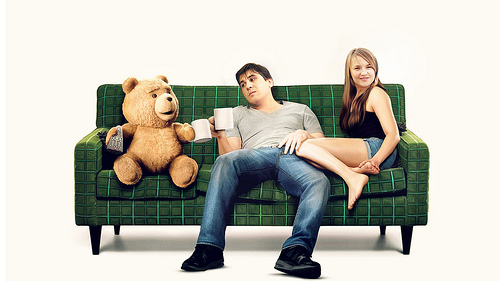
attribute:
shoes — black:
[165, 231, 330, 275]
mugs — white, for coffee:
[180, 104, 235, 146]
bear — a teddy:
[108, 74, 190, 196]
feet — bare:
[333, 148, 390, 210]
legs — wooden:
[80, 222, 136, 249]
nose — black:
[163, 94, 185, 108]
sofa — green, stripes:
[86, 79, 430, 229]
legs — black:
[72, 218, 443, 267]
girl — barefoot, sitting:
[300, 49, 400, 169]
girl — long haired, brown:
[323, 41, 404, 198]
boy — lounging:
[178, 54, 328, 225]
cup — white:
[199, 96, 262, 138]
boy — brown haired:
[208, 70, 325, 234]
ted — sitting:
[94, 68, 241, 188]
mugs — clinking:
[175, 96, 258, 149]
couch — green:
[85, 92, 442, 251]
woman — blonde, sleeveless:
[300, 51, 430, 218]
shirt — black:
[331, 87, 396, 138]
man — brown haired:
[199, 69, 371, 257]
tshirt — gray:
[210, 98, 314, 141]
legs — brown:
[50, 215, 138, 255]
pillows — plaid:
[100, 152, 428, 201]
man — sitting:
[185, 74, 360, 255]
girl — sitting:
[284, 46, 445, 201]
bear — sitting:
[92, 70, 213, 185]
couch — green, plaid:
[88, 79, 453, 213]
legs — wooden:
[83, 204, 439, 264]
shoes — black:
[178, 243, 322, 278]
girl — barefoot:
[286, 65, 406, 221]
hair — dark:
[234, 63, 276, 76]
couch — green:
[71, 82, 432, 258]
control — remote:
[102, 125, 127, 152]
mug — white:
[191, 119, 212, 145]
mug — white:
[209, 104, 234, 132]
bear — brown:
[101, 77, 198, 197]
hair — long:
[342, 49, 382, 110]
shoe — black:
[182, 246, 226, 275]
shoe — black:
[274, 242, 324, 279]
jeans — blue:
[194, 142, 334, 256]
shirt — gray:
[212, 98, 321, 148]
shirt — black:
[337, 90, 383, 139]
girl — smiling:
[301, 47, 399, 214]